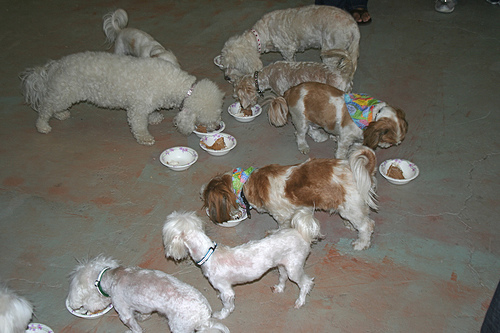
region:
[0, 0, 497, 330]
more than several hungry pets chow down in front of two people's feet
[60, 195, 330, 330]
two little white yapster pups, sheared but for heads+tails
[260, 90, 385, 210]
the fluffy, curled tails of two yapster dogs wearing bandanas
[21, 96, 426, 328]
dog dishes are the people's china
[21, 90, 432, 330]
though the bowls may be glass & not porcelain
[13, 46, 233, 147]
a mighty long toy poodle, torso extended, chowing down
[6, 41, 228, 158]
toy poodle is white with metallic collar, also wiry fluffy tail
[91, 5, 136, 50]
another fluffy curled tail on tiny white dog bringing up rear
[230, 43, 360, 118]
a tiny velvety looking dog w/ a hard black punky-people collar beside a sheared toy poodle w/ remaining furry head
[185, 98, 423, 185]
all visible dog food is chunk pat type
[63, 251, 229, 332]
little white puppy eating from bowl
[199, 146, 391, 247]
brown and white dog eating from bowl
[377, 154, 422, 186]
a white bowl with dog food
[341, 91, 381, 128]
a multi-colored scarf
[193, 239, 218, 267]
a white and green dog collar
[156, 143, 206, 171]
a white empty bowl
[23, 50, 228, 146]
a white poodle eating from bowl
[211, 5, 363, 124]
two brown dogs eating from bowl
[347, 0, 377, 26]
a foot wearing a sandal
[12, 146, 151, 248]
the off white and peach colored ground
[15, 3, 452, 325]
a passle of poodles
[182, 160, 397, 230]
a brown & white dog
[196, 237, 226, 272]
the dog's collar is white with blue trim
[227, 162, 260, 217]
the dog is wearing a bandana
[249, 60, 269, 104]
this dog has a black & studded collar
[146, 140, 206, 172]
the dish is white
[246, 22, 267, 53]
this dog's collar is white with red spots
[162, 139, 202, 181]
the dish has purple flowers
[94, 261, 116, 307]
this dog has a white collar with green trim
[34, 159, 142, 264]
the floor appears to be slate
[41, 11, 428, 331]
dogs eating food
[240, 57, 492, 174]
dog with a bandanna on it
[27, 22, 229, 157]
curly haired white dog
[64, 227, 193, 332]
white dog eating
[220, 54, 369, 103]
white dog eating food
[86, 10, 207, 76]
dog eating good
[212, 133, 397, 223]
brown and white dog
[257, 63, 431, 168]
brown and white dog with a bandanna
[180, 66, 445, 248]
two dogs with the same coat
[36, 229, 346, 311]
two white dogs eating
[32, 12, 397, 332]
Multiple dogs are standing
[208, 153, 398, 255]
Dog is brown and white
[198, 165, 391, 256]
Dog has brown spots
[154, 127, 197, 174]
White bowls with pink border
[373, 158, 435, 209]
Brown food in bowl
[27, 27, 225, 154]
Dog is eating from a bowl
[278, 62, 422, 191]
A dog is wearing a bandana around its neck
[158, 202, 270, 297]
The dog is wearing a white and black collar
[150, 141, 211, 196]
The bowl is on white and orange cement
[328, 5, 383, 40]
Person with black sandals